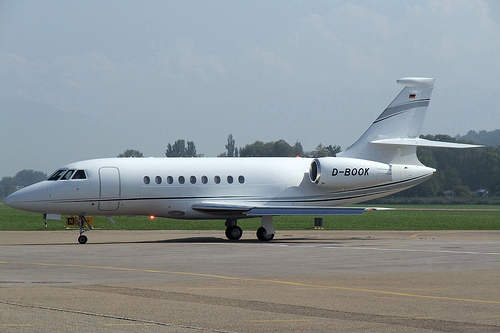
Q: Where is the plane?
A: Airport.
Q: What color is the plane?
A: White.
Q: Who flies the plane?
A: Pilot.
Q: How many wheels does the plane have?
A: 3.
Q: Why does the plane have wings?
A: To fly.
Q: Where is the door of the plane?
A: Left side.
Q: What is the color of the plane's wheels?
A: Black.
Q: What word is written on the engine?
A: D-BOOK.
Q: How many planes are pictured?
A: One.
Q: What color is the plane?
A: White.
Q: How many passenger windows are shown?
A: Nine.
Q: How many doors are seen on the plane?
A: One.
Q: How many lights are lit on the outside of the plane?
A: One.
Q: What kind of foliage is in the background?
A: Trees.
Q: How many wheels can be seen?
A: Three.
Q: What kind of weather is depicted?
A: Cloudy.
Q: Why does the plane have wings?
A: To fly.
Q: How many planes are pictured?
A: One.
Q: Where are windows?
A: On the plane.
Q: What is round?
A: Windows on side of the plane.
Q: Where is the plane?
A: On a runway.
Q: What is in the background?
A: Trees.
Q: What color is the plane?
A: White.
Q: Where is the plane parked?
A: On the ground.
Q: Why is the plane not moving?
A: It is waiting for something.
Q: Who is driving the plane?
A: Pilot.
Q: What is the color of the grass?
A: Green.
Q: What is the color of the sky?
A: Gray.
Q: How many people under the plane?
A: No one.